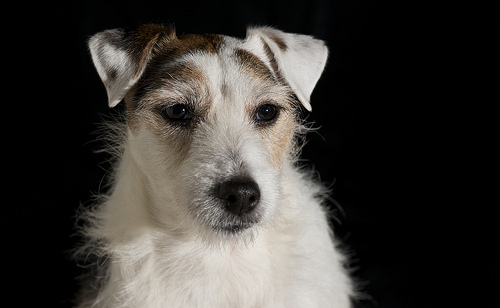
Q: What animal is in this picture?
A: Dog.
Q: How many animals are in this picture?
A: One.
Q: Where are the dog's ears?
A: On its head.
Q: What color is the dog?
A: White.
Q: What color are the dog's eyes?
A: Black.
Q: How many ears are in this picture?
A: Two.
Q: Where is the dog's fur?
A: On its body.